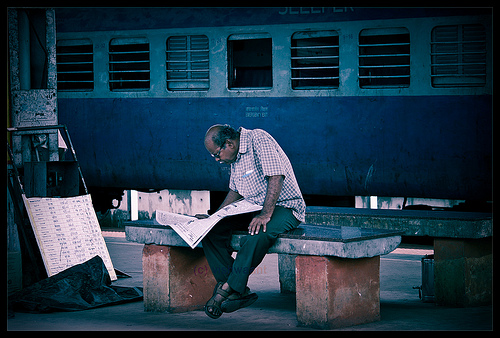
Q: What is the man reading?
A: A newspaper.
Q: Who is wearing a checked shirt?
A: The man.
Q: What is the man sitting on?
A: A bench.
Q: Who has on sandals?
A: The man.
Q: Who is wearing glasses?
A: The man.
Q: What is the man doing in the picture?
A: Reading a newspaper.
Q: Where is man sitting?
A: On the bench.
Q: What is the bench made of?
A: Concrete.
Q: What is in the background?
A: Train car.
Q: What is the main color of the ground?
A: Gray.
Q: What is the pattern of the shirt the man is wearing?
A: Plaid.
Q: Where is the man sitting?
A: On the bench.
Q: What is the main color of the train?
A: Gray.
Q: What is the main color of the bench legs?
A: Red.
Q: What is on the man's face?
A: Glasses.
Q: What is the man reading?
A: Newspaper.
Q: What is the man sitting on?
A: Bench.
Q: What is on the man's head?
A: Glasses.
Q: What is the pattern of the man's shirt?
A: Check.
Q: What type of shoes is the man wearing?
A: Sandals.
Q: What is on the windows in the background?
A: Bars.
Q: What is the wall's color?
A: Blue.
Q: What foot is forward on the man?
A: Left.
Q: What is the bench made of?
A: Stone.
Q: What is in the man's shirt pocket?
A: Handkerchief.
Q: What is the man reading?
A: The newspaper.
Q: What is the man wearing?
A: Glasses.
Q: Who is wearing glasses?
A: The man.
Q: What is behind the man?
A: Windows.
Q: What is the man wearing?
A: Checkered shirt.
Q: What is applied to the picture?
A: A filter.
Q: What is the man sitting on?
A: A bench.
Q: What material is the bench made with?
A: Granite.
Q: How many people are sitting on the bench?
A: 1.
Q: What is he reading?
A: A newspaper.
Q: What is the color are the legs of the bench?
A: Reddish.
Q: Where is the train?
A: Behind the man.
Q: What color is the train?
A: Blue.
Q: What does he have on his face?
A: Glasses.